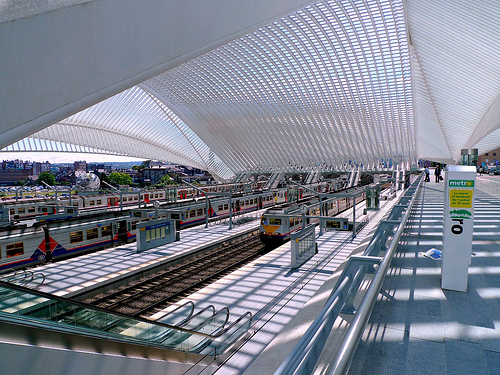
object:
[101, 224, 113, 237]
window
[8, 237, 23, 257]
window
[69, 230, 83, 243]
window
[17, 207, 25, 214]
window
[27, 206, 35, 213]
window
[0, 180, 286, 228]
train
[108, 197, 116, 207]
window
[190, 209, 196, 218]
window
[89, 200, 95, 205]
window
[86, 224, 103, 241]
train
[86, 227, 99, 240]
window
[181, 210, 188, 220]
window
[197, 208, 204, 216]
window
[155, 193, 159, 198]
window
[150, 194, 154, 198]
window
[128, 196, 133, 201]
window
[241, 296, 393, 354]
scene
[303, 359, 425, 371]
scene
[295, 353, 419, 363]
scene